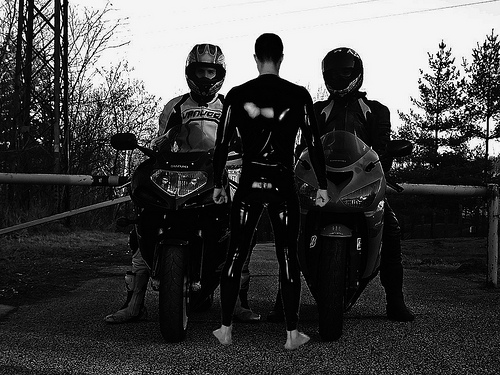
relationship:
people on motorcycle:
[108, 21, 420, 352] [101, 124, 238, 339]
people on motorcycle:
[108, 21, 420, 352] [282, 126, 413, 340]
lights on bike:
[106, 127, 247, 209] [108, 130, 257, 343]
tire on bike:
[162, 245, 199, 336] [127, 147, 220, 337]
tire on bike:
[315, 220, 355, 330] [290, 136, 384, 328]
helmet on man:
[322, 47, 363, 97] [313, 48, 398, 150]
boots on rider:
[98, 241, 162, 328] [104, 37, 234, 336]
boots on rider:
[381, 230, 415, 325] [301, 47, 421, 328]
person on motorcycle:
[303, 30, 414, 335] [289, 129, 384, 335]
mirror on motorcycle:
[108, 130, 140, 148] [100, 125, 252, 340]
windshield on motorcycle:
[319, 143, 384, 181] [272, 131, 424, 336]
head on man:
[253, 33, 285, 66] [203, 34, 329, 355]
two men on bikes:
[127, 35, 418, 337] [103, 133, 417, 341]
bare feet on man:
[207, 326, 311, 352] [203, 34, 329, 355]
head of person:
[248, 35, 291, 84] [201, 26, 322, 349]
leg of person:
[271, 205, 308, 350] [208, 28, 324, 365]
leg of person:
[211, 196, 265, 346] [208, 28, 324, 365]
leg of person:
[206, 196, 264, 356] [194, 22, 324, 337]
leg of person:
[271, 253, 308, 354] [194, 22, 324, 337]